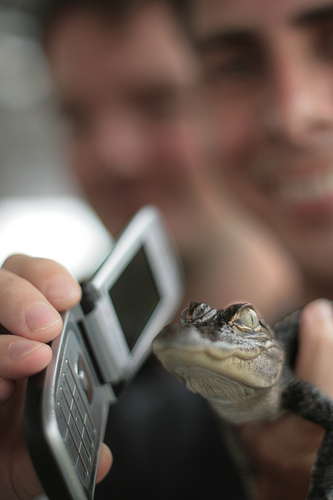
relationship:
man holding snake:
[183, 21, 333, 291] [171, 292, 324, 435]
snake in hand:
[171, 292, 324, 435] [299, 312, 330, 431]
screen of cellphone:
[107, 229, 156, 330] [59, 217, 153, 487]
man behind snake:
[0, 0, 333, 500] [171, 292, 324, 435]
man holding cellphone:
[183, 21, 333, 291] [59, 217, 153, 487]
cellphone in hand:
[59, 217, 153, 487] [0, 253, 84, 499]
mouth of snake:
[155, 320, 258, 375] [171, 292, 324, 435]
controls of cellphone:
[50, 364, 95, 466] [59, 217, 153, 487]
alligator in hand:
[180, 315, 329, 409] [299, 312, 330, 431]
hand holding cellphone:
[0, 253, 84, 499] [21, 202, 187, 500]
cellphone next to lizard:
[59, 217, 153, 487] [150, 299, 333, 500]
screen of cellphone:
[107, 229, 156, 330] [21, 202, 187, 500]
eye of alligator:
[235, 305, 262, 334] [180, 315, 329, 409]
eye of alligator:
[230, 311, 260, 328] [180, 315, 329, 409]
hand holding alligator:
[299, 312, 330, 431] [180, 315, 329, 409]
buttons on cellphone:
[61, 369, 91, 460] [21, 202, 187, 500]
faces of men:
[160, 49, 329, 139] [44, 5, 327, 240]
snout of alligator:
[157, 329, 199, 357] [180, 315, 329, 409]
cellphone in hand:
[21, 202, 187, 500] [0, 253, 84, 499]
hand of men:
[0, 253, 84, 499] [28, 5, 300, 500]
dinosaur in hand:
[152, 294, 316, 426] [299, 312, 330, 431]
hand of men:
[299, 312, 330, 431] [28, 5, 300, 500]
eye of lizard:
[230, 311, 260, 328] [145, 299, 310, 394]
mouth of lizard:
[155, 320, 258, 375] [145, 299, 310, 394]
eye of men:
[132, 86, 192, 116] [28, 5, 300, 500]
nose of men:
[92, 96, 148, 196] [28, 5, 300, 500]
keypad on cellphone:
[53, 351, 116, 484] [21, 202, 187, 500]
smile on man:
[263, 152, 332, 199] [183, 21, 333, 291]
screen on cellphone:
[107, 229, 156, 330] [21, 202, 187, 500]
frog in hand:
[156, 303, 299, 403] [299, 312, 330, 431]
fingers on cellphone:
[11, 263, 96, 372] [21, 202, 187, 500]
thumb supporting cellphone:
[92, 432, 117, 480] [21, 202, 187, 500]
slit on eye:
[249, 310, 255, 326] [230, 311, 260, 328]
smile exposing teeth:
[263, 152, 332, 199] [291, 178, 332, 203]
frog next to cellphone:
[156, 303, 299, 403] [21, 202, 187, 500]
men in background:
[44, 5, 327, 240] [37, 29, 320, 250]